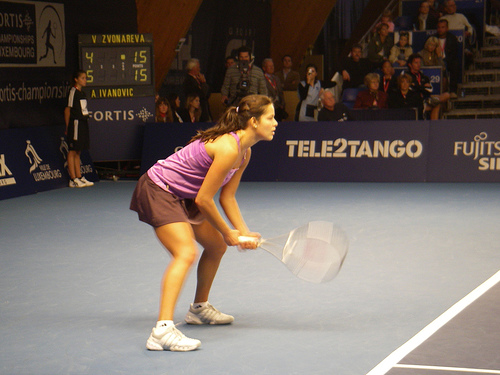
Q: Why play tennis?
A: To find the winner.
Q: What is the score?
A: 15 to 15.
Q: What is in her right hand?
A: A racket.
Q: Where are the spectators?
A: In the bleachers.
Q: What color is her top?
A: Purple.